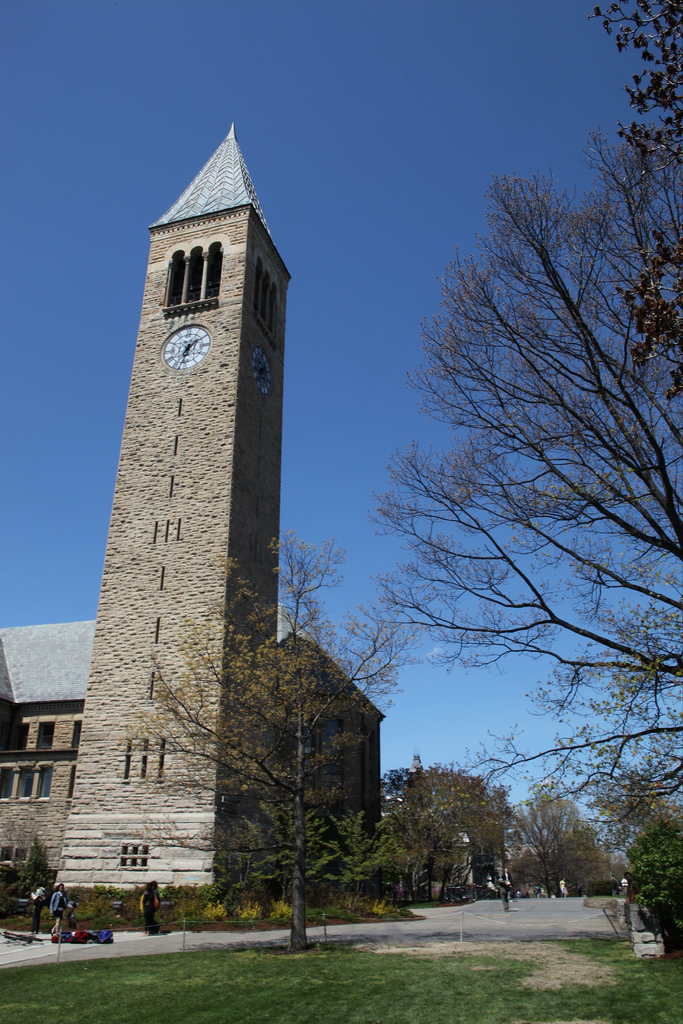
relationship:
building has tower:
[0, 605, 389, 898] [57, 84, 293, 889]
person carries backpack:
[31, 882, 45, 936] [39, 889, 44, 902]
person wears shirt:
[133, 874, 175, 941] [147, 892, 160, 908]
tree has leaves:
[120, 529, 423, 954] [117, 531, 424, 853]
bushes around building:
[8, 830, 407, 916] [10, 115, 396, 910]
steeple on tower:
[144, 117, 293, 280] [136, 263, 241, 716]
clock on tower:
[158, 322, 211, 371] [46, 113, 292, 917]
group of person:
[23, 861, 184, 962] [28, 877, 49, 939]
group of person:
[23, 861, 184, 962] [49, 879, 72, 951]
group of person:
[23, 861, 184, 962] [138, 875, 167, 943]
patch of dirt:
[511, 968, 553, 994] [342, 913, 620, 1012]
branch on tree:
[441, 727, 644, 785] [374, 137, 668, 802]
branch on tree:
[436, 620, 589, 694] [374, 137, 668, 802]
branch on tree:
[364, 463, 561, 628] [374, 137, 668, 802]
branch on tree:
[573, 192, 615, 311] [374, 137, 668, 802]